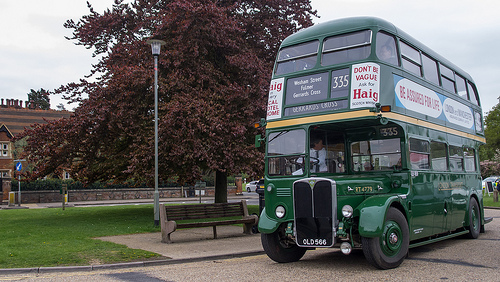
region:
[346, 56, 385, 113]
Sign for advertising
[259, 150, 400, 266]
Old truck grill and car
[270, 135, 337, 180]
driver on right side not from usa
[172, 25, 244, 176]
beautiful tree healthy and colorfull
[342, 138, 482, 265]
green buss polished up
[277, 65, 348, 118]
Buss number and location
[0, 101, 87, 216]
Home next to bus stop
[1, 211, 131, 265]
Landscaped grass on ground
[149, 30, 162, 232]
Tall light post gray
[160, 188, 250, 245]
Bench to sit on on top of sidewalk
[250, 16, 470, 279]
green passenger bus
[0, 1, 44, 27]
white clouds in blue sky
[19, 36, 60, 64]
white clouds in blue sky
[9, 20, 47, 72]
white clouds in blue sky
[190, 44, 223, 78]
brown tree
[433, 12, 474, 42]
white clouds in blue sky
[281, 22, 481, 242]
green bus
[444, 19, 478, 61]
white clouds in blue sky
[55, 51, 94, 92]
white clouds in blue sky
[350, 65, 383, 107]
red and white sign advertisement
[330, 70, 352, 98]
bus route numbers 335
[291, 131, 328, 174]
bus driver looking back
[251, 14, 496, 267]
double decker bus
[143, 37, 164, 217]
tall light pole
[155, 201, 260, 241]
wooden park bench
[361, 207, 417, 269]
rubber tire with green hub cap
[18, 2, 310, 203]
red leaf maple tree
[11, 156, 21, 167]
little blue flag with an arrow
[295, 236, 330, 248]
license plate with white lettering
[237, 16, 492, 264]
bus on a street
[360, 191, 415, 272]
tire on a bus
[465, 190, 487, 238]
tire on a bus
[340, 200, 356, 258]
lights on a bus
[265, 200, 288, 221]
light on a bus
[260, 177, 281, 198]
light on a bus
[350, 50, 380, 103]
sign on a bus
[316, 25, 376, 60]
windows on a bus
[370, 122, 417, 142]
number on a bus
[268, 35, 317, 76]
windows on a bus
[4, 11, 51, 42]
white clouds in blue sky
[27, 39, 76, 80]
white clouds in blue sky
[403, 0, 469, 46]
white clouds in blue sky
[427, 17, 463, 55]
white clouds in blue sky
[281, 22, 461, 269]
green and white passenger bus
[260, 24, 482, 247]
green and white bus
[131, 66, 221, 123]
brown tree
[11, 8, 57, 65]
white clouds against blue sky